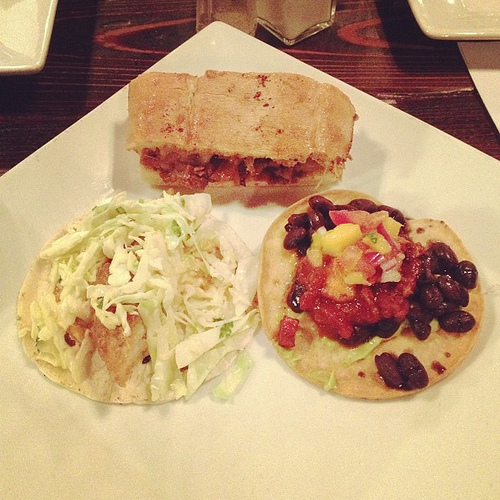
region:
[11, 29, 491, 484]
A large white plate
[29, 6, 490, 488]
The plate is white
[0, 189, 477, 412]
There are two tortillas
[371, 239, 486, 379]
Brown pinto beans on the tortilla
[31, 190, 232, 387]
Lettuce on the tortilla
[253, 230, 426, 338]
The salsa is red and yellow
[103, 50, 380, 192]
Bread with an inner filling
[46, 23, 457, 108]
The table is dark brown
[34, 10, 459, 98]
The counter is made of wood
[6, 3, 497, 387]
There are many white plates on the table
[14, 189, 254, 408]
Small round tortilla with toppings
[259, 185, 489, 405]
Tiny size tortilla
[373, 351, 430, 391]
Red beans on tortilla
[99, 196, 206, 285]
Shreds of lettuce or cabbage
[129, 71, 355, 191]
Rectangular size sandwich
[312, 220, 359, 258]
Small piece of pineapple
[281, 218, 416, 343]
Red picante sauce on torilla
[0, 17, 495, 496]
Dinner plate with a meal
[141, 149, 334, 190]
Red type of meat on bread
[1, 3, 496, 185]
A brown wooden table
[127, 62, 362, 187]
half sandwich on white plate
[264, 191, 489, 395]
veggie taco on white plate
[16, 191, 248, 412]
chicken taco on white plate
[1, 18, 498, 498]
white square dinner plate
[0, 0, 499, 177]
wooden table under plate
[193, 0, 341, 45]
salt and pepper shakers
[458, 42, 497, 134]
white napkin next toplate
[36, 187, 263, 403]
lettuce on taco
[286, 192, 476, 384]
beans on veggie taco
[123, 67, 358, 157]
toasted bread of sandwich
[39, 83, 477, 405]
Food on a white square plate.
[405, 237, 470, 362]
Black beans on a taco.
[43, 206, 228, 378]
The taco has lettuce on top of it.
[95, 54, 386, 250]
A sandwich with bacon on it.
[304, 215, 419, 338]
The pita bread has salsa on it.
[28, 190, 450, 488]
The plate is white and shaped like a square.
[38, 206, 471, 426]
Two pitas on the plate.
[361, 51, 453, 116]
The table is brown and wooden.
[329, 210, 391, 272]
Chopped fruits on the salsa.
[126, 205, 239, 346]
The lettuce is white and green.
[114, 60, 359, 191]
a meat and sauce sandwich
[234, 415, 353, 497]
a white table cloth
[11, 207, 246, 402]
a white tortilla topped with lettuce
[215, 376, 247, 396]
a shred of lettuce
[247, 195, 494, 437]
a wheat tortilla with beans and salsa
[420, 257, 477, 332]
red kidney beans on a tortilla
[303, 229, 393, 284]
pineapple salsa on red salsa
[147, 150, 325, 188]
meat and sauce in a sandwich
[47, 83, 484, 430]
mexican food on a table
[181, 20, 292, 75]
the corner of a white plate